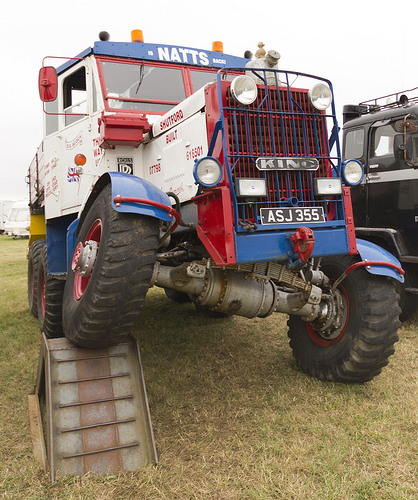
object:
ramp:
[47, 335, 155, 480]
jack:
[27, 331, 158, 486]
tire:
[61, 183, 160, 349]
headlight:
[231, 75, 258, 105]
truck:
[24, 29, 403, 383]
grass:
[0, 237, 417, 499]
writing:
[156, 48, 208, 66]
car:
[341, 89, 418, 323]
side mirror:
[38, 68, 58, 102]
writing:
[415, 214, 418, 223]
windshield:
[99, 61, 239, 113]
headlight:
[309, 82, 332, 111]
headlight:
[197, 159, 221, 184]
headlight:
[344, 161, 363, 184]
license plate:
[260, 206, 325, 225]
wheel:
[73, 218, 106, 300]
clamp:
[289, 226, 314, 264]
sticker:
[160, 109, 184, 130]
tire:
[286, 254, 402, 383]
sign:
[256, 157, 320, 170]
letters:
[268, 208, 319, 222]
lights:
[131, 29, 145, 43]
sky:
[0, 0, 418, 201]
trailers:
[0, 204, 32, 239]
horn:
[399, 94, 409, 104]